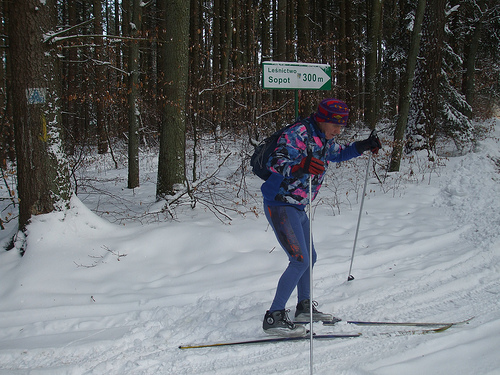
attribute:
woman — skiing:
[235, 104, 379, 330]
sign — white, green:
[254, 51, 340, 97]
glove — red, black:
[370, 126, 390, 161]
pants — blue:
[247, 202, 323, 314]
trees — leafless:
[3, 6, 252, 212]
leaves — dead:
[86, 155, 116, 167]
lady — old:
[245, 91, 412, 309]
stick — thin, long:
[301, 174, 327, 371]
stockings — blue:
[252, 208, 340, 306]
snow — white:
[6, 197, 474, 375]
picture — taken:
[5, 5, 494, 359]